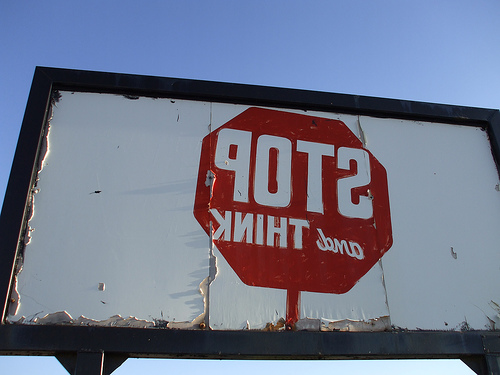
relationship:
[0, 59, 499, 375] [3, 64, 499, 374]
frame with frame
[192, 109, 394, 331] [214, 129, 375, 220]
stop sign drawing has stop letters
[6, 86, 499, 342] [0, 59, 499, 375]
paper peeling off frame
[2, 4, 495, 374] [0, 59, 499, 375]
sky above frame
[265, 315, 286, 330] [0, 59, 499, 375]
spot on frame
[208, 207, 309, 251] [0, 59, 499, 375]
word think on frame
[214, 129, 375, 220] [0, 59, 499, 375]
stop letters on frame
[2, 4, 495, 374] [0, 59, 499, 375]
sky showing under frame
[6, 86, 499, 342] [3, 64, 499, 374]
paper by frame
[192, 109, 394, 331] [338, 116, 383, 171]
stop sign drawing has edge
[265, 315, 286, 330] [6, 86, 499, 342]
spot on paper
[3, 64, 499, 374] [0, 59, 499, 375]
frame on frame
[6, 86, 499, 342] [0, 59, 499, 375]
paper on frame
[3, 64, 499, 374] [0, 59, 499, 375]
frame around frame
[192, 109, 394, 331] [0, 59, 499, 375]
stop sign drawing on frame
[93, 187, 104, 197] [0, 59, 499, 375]
dirt on frame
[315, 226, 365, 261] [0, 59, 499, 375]
word and on frame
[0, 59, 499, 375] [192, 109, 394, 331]
frame has stop sign drawing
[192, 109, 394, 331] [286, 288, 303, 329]
stop sign drawing has pole drawing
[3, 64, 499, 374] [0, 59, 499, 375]
frame of frame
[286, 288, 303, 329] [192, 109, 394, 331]
pole drawing holding stop sign drawing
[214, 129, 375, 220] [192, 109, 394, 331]
stop letters on stop sign drawing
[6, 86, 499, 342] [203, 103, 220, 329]
paper has line